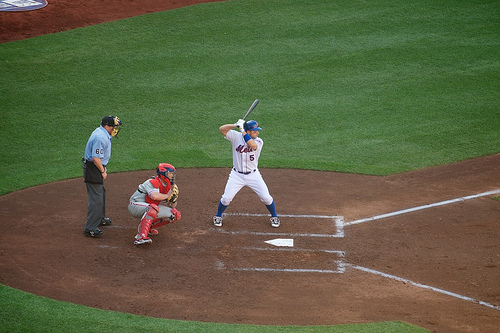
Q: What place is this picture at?
A: It is at the field.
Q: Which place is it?
A: It is a field.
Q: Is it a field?
A: Yes, it is a field.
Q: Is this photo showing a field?
A: Yes, it is showing a field.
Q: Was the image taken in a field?
A: Yes, it was taken in a field.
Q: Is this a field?
A: Yes, it is a field.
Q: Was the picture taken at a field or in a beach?
A: It was taken at a field.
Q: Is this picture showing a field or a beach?
A: It is showing a field.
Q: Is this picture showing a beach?
A: No, the picture is showing a field.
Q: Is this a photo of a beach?
A: No, the picture is showing a field.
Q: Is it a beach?
A: No, it is a field.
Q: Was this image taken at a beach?
A: No, the picture was taken in a field.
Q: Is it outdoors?
A: Yes, it is outdoors.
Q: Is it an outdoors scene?
A: Yes, it is outdoors.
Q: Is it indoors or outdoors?
A: It is outdoors.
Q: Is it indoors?
A: No, it is outdoors.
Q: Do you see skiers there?
A: No, there are no skiers.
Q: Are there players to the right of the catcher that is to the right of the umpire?
A: Yes, there are players to the right of the catcher.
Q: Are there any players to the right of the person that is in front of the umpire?
A: Yes, there are players to the right of the catcher.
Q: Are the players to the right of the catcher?
A: Yes, the players are to the right of the catcher.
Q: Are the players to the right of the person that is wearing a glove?
A: Yes, the players are to the right of the catcher.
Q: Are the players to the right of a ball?
A: No, the players are to the right of the catcher.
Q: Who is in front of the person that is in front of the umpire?
A: The players are in front of the catcher.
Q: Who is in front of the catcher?
A: The players are in front of the catcher.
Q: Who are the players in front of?
A: The players are in front of the catcher.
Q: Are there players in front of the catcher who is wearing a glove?
A: Yes, there are players in front of the catcher.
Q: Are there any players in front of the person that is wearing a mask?
A: Yes, there are players in front of the catcher.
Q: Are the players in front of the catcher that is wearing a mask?
A: Yes, the players are in front of the catcher.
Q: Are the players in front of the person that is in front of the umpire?
A: Yes, the players are in front of the catcher.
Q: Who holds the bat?
A: The players hold the bat.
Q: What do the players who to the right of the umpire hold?
A: The players hold the bat.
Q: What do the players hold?
A: The players hold the bat.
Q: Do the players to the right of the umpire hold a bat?
A: Yes, the players hold a bat.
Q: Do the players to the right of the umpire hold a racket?
A: No, the players hold a bat.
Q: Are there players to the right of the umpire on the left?
A: Yes, there are players to the right of the umpire.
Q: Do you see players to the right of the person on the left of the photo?
A: Yes, there are players to the right of the umpire.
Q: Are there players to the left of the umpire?
A: No, the players are to the right of the umpire.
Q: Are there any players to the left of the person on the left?
A: No, the players are to the right of the umpire.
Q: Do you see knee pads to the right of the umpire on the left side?
A: No, there are players to the right of the umpire.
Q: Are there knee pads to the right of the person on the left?
A: No, there are players to the right of the umpire.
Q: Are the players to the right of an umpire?
A: Yes, the players are to the right of an umpire.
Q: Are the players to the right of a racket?
A: No, the players are to the right of an umpire.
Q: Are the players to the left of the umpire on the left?
A: No, the players are to the right of the umpire.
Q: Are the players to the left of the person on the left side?
A: No, the players are to the right of the umpire.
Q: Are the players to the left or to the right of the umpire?
A: The players are to the right of the umpire.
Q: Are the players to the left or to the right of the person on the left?
A: The players are to the right of the umpire.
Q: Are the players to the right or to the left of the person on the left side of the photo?
A: The players are to the right of the umpire.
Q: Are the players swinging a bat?
A: Yes, the players are swinging a bat.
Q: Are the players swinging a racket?
A: No, the players are swinging a bat.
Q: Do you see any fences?
A: No, there are no fences.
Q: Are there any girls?
A: No, there are no girls.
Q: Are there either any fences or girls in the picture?
A: No, there are no girls or fences.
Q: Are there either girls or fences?
A: No, there are no girls or fences.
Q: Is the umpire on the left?
A: Yes, the umpire is on the left of the image.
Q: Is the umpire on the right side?
A: No, the umpire is on the left of the image.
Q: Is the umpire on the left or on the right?
A: The umpire is on the left of the image.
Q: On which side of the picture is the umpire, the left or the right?
A: The umpire is on the left of the image.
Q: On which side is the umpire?
A: The umpire is on the left of the image.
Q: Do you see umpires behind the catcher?
A: Yes, there is an umpire behind the catcher.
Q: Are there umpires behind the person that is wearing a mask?
A: Yes, there is an umpire behind the catcher.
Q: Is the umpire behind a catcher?
A: Yes, the umpire is behind a catcher.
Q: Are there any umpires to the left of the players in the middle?
A: Yes, there is an umpire to the left of the players.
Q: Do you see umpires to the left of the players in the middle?
A: Yes, there is an umpire to the left of the players.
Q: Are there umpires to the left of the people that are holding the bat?
A: Yes, there is an umpire to the left of the players.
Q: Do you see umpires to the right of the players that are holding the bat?
A: No, the umpire is to the left of the players.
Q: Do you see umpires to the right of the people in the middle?
A: No, the umpire is to the left of the players.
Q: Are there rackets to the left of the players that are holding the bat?
A: No, there is an umpire to the left of the players.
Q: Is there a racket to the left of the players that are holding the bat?
A: No, there is an umpire to the left of the players.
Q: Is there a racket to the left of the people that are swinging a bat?
A: No, there is an umpire to the left of the players.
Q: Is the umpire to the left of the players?
A: Yes, the umpire is to the left of the players.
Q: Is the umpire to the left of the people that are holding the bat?
A: Yes, the umpire is to the left of the players.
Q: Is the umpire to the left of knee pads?
A: No, the umpire is to the left of the players.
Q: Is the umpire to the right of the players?
A: No, the umpire is to the left of the players.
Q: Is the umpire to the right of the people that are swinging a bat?
A: No, the umpire is to the left of the players.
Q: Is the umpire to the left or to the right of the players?
A: The umpire is to the left of the players.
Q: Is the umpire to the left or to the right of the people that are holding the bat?
A: The umpire is to the left of the players.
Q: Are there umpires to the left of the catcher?
A: Yes, there is an umpire to the left of the catcher.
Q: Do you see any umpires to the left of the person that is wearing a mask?
A: Yes, there is an umpire to the left of the catcher.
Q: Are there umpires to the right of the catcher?
A: No, the umpire is to the left of the catcher.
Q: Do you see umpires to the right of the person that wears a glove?
A: No, the umpire is to the left of the catcher.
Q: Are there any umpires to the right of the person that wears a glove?
A: No, the umpire is to the left of the catcher.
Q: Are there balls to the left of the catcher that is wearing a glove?
A: No, there is an umpire to the left of the catcher.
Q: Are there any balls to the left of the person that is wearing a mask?
A: No, there is an umpire to the left of the catcher.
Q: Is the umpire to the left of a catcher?
A: Yes, the umpire is to the left of a catcher.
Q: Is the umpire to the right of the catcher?
A: No, the umpire is to the left of the catcher.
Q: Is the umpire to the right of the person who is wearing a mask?
A: No, the umpire is to the left of the catcher.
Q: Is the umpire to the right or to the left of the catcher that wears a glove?
A: The umpire is to the left of the catcher.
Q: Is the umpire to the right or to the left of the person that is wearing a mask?
A: The umpire is to the left of the catcher.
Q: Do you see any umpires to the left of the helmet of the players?
A: Yes, there is an umpire to the left of the helmet.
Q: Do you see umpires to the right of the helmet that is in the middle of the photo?
A: No, the umpire is to the left of the helmet.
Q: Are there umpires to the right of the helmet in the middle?
A: No, the umpire is to the left of the helmet.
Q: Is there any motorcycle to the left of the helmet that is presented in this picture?
A: No, there is an umpire to the left of the helmet.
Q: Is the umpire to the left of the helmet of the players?
A: Yes, the umpire is to the left of the helmet.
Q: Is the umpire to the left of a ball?
A: No, the umpire is to the left of the helmet.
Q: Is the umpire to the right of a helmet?
A: No, the umpire is to the left of a helmet.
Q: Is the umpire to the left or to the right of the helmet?
A: The umpire is to the left of the helmet.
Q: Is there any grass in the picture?
A: Yes, there is grass.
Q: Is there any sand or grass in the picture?
A: Yes, there is grass.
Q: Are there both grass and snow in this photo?
A: No, there is grass but no snow.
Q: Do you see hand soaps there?
A: No, there are no hand soaps.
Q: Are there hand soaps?
A: No, there are no hand soaps.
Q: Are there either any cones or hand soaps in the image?
A: No, there are no hand soaps or cones.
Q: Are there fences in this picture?
A: No, there are no fences.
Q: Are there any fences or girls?
A: No, there are no fences or girls.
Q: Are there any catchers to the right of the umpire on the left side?
A: Yes, there is a catcher to the right of the umpire.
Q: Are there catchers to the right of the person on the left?
A: Yes, there is a catcher to the right of the umpire.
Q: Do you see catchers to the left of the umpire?
A: No, the catcher is to the right of the umpire.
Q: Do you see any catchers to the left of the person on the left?
A: No, the catcher is to the right of the umpire.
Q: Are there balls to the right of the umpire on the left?
A: No, there is a catcher to the right of the umpire.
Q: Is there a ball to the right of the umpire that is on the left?
A: No, there is a catcher to the right of the umpire.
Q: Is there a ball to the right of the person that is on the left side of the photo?
A: No, there is a catcher to the right of the umpire.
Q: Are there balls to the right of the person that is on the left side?
A: No, there is a catcher to the right of the umpire.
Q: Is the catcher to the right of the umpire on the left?
A: Yes, the catcher is to the right of the umpire.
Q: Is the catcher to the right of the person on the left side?
A: Yes, the catcher is to the right of the umpire.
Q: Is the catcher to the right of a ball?
A: No, the catcher is to the right of the umpire.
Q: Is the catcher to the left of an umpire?
A: No, the catcher is to the right of an umpire.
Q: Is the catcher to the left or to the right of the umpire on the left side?
A: The catcher is to the right of the umpire.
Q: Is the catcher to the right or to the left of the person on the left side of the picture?
A: The catcher is to the right of the umpire.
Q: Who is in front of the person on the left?
A: The catcher is in front of the umpire.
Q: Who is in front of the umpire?
A: The catcher is in front of the umpire.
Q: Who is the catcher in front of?
A: The catcher is in front of the umpire.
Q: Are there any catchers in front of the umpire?
A: Yes, there is a catcher in front of the umpire.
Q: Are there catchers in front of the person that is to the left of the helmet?
A: Yes, there is a catcher in front of the umpire.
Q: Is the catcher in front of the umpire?
A: Yes, the catcher is in front of the umpire.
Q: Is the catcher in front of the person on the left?
A: Yes, the catcher is in front of the umpire.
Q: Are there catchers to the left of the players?
A: Yes, there is a catcher to the left of the players.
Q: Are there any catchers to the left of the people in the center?
A: Yes, there is a catcher to the left of the players.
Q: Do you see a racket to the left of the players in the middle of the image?
A: No, there is a catcher to the left of the players.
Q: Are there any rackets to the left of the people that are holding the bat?
A: No, there is a catcher to the left of the players.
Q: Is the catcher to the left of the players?
A: Yes, the catcher is to the left of the players.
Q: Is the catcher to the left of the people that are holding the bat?
A: Yes, the catcher is to the left of the players.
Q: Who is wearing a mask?
A: The catcher is wearing a mask.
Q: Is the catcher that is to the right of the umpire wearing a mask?
A: Yes, the catcher is wearing a mask.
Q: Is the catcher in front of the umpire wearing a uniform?
A: No, the catcher is wearing a mask.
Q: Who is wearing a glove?
A: The catcher is wearing a glove.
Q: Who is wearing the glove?
A: The catcher is wearing a glove.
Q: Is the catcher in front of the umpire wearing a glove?
A: Yes, the catcher is wearing a glove.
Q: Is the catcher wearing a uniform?
A: No, the catcher is wearing a glove.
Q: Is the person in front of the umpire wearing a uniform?
A: No, the catcher is wearing a glove.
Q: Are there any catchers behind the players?
A: Yes, there is a catcher behind the players.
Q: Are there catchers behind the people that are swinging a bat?
A: Yes, there is a catcher behind the players.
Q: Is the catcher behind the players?
A: Yes, the catcher is behind the players.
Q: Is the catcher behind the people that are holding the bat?
A: Yes, the catcher is behind the players.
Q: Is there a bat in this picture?
A: Yes, there is a bat.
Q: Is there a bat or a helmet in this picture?
A: Yes, there is a bat.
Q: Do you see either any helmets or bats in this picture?
A: Yes, there is a bat.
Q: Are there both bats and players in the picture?
A: Yes, there are both a bat and a player.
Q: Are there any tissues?
A: No, there are no tissues.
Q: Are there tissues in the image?
A: No, there are no tissues.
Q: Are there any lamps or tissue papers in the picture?
A: No, there are no tissue papers or lamps.